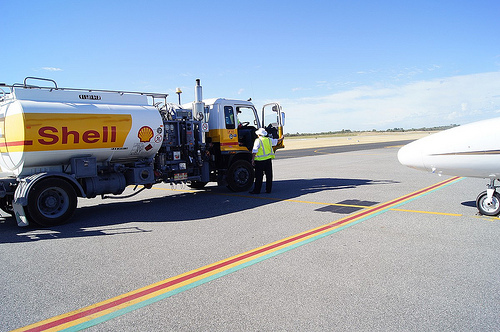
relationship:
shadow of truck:
[173, 194, 211, 235] [16, 85, 242, 199]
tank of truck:
[6, 78, 155, 148] [16, 85, 242, 199]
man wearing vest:
[254, 127, 278, 190] [256, 140, 271, 161]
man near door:
[254, 127, 278, 190] [247, 100, 287, 121]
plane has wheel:
[396, 119, 484, 189] [475, 183, 497, 215]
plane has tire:
[396, 119, 484, 189] [475, 183, 497, 215]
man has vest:
[254, 127, 278, 190] [256, 140, 271, 161]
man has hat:
[254, 127, 278, 190] [245, 123, 262, 139]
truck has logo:
[16, 85, 242, 199] [128, 118, 162, 146]